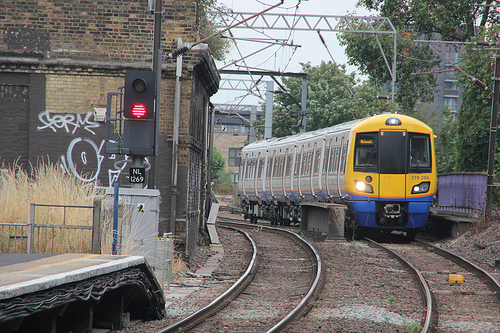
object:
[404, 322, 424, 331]
grass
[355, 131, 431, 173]
front windows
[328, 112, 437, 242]
engine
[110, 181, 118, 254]
pole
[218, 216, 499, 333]
dirt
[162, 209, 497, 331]
tracks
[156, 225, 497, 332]
railroad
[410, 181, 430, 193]
headlights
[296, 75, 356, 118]
bush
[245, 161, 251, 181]
window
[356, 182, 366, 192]
headlight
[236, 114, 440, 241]
train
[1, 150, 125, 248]
plant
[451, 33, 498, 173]
plant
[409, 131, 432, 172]
window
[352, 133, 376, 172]
window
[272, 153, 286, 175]
window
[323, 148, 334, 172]
window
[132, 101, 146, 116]
light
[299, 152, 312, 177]
window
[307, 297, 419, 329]
rocks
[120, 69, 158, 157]
signal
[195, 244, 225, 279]
cement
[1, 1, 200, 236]
brick wall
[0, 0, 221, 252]
building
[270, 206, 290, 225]
wheels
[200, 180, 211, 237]
pipes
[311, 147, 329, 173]
windows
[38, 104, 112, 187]
graffiti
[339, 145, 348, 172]
window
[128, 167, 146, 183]
nl 1269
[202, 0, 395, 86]
scaffolding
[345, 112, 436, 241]
front end